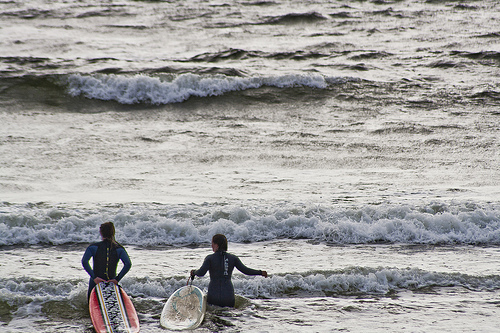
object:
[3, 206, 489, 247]
waves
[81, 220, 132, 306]
girl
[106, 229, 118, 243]
ponytail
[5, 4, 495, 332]
ocean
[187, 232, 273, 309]
girl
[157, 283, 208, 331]
surfboard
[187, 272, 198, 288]
rope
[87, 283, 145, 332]
surfboard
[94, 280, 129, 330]
stripe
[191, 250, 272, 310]
wet suit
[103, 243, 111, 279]
detailing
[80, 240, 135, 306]
wet suit